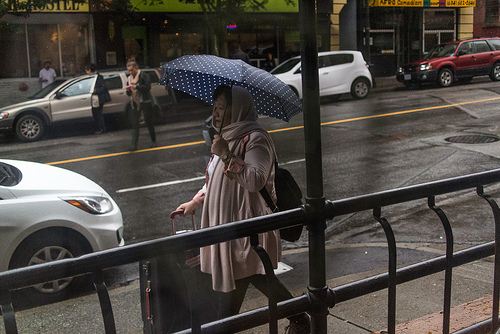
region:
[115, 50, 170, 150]
Woman crossing street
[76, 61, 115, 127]
Woman getting into car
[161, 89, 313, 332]
Woman carrying blue polka dot umbrella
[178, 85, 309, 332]
Woman rolling suitcase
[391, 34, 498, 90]
Red car parked behind white car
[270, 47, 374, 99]
White car parked behind champagne car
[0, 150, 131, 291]
Woman passing by white car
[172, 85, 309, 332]
Woman carrying backpack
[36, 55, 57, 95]
Man standing in front of building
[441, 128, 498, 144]
Manhole cover on road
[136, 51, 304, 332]
woman pulling suitcase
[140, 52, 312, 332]
woman with black backpack and holding an umbrella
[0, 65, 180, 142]
car with the door open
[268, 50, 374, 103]
white car parked on the street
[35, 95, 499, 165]
yellow line across de road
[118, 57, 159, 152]
woman crossing the street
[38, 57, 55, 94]
man wearing white shirt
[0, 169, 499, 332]
black metal fence on the sidewalk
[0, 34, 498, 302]
four cars parked on the street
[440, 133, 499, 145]
metal manhole on the road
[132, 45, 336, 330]
a woman holds an umbrella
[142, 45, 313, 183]
woman holds an umbrella in his left hand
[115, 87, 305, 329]
woman carry a suitcase in her right hand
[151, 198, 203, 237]
hand holding the handle of a suitcase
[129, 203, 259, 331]
suitcase is big and wide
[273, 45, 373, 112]
a white car parking on the side of the street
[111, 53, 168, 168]
woman crossing the street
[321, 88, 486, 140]
a yellow line painted in center of the street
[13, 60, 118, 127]
a man in the doorstep of a car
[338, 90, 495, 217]
road is wet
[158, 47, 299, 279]
a woman holding a umbrella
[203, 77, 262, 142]
a woman with black hair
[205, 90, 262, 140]
a woman with a scarf around her head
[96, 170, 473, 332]
a black iron fence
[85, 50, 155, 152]
a woman crossing a street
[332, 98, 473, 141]
a yellow line painted on a road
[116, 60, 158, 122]
a woman wearing a scarf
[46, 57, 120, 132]
a woman getting into a car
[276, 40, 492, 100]
two cars parked on the side of a road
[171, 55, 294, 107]
a blue umbrella with white dots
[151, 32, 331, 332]
woman holding blue polka dot umbrella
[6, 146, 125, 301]
front right side of white car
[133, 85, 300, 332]
woman walking with suitcase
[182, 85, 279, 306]
woman wearing gray hood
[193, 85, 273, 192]
woman wearing watch on left wrist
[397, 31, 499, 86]
red sports utility vehicle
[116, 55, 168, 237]
woman looking at phone while crossing street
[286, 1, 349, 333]
dark metal fence pole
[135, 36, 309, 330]
woman wearing beige knit sweater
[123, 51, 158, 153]
woman with light brown bun